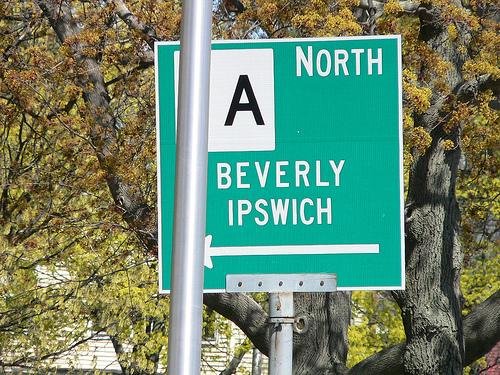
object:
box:
[173, 48, 276, 152]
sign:
[153, 33, 406, 294]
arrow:
[204, 233, 380, 269]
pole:
[164, 0, 213, 375]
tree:
[1, 0, 499, 374]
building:
[0, 234, 270, 375]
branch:
[37, 0, 270, 358]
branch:
[104, 0, 163, 53]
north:
[295, 44, 383, 77]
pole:
[266, 291, 297, 374]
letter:
[216, 162, 232, 189]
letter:
[235, 161, 252, 189]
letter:
[254, 160, 272, 187]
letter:
[274, 160, 289, 188]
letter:
[294, 160, 311, 188]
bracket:
[226, 273, 339, 293]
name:
[216, 159, 346, 190]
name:
[226, 196, 334, 226]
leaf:
[66, 31, 97, 53]